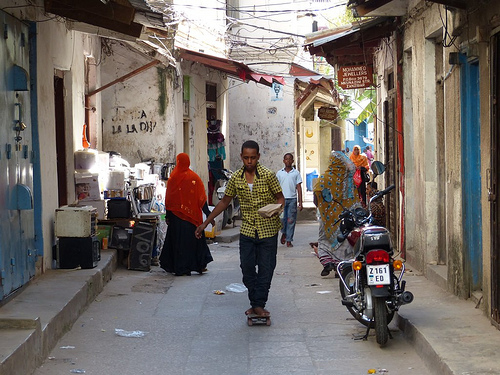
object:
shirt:
[223, 162, 284, 239]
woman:
[158, 151, 216, 276]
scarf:
[164, 152, 207, 229]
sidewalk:
[0, 247, 117, 375]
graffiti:
[112, 110, 157, 135]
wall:
[103, 43, 182, 199]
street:
[5, 0, 500, 375]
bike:
[321, 161, 414, 348]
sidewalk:
[375, 247, 499, 373]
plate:
[366, 264, 391, 286]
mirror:
[321, 187, 334, 202]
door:
[460, 50, 483, 304]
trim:
[457, 54, 484, 295]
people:
[158, 138, 376, 324]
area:
[8, 0, 498, 364]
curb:
[395, 309, 452, 373]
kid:
[194, 140, 285, 319]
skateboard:
[245, 308, 272, 326]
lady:
[159, 152, 215, 276]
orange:
[165, 152, 207, 228]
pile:
[52, 146, 169, 272]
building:
[0, 0, 186, 375]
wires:
[146, 0, 357, 65]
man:
[275, 153, 302, 247]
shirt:
[276, 167, 303, 199]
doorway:
[459, 52, 482, 300]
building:
[302, 0, 500, 374]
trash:
[113, 283, 331, 339]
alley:
[0, 0, 498, 372]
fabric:
[165, 152, 207, 227]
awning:
[174, 44, 286, 88]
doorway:
[205, 80, 223, 201]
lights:
[352, 249, 401, 270]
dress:
[158, 212, 214, 276]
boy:
[193, 140, 286, 318]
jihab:
[165, 152, 207, 229]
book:
[258, 204, 284, 219]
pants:
[239, 231, 278, 309]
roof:
[289, 61, 342, 110]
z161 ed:
[369, 267, 387, 282]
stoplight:
[366, 250, 390, 264]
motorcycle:
[319, 173, 416, 353]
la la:
[112, 124, 138, 134]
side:
[100, 40, 174, 200]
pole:
[395, 83, 405, 262]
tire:
[373, 293, 388, 345]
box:
[54, 203, 98, 237]